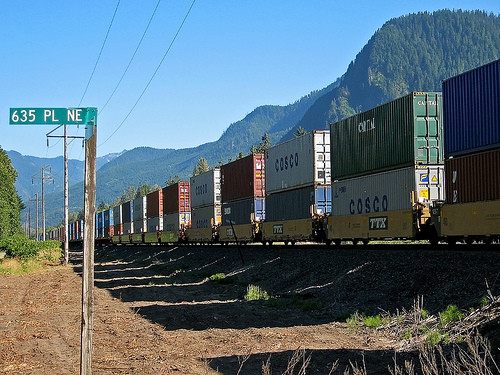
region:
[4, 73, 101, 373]
an address sign with green and white lettering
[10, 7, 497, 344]
a train with double decker cars on it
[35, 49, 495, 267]
a double decker train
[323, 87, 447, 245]
a double decker train with a green top tank and gray lower one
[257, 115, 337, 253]
double decker train cars with a gray one on top and blue on the bottom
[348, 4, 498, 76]
a distant mountain of pine trees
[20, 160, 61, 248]
utility poles in the distance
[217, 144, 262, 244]
a red train car on top and a blue one below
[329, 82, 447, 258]
a green rail car on top and grey one below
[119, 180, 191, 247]
four train cars holding double units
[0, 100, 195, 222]
the sign is green and white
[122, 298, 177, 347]
dirt is on the ground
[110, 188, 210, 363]
train cars cast shadows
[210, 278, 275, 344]
grass is in the dirt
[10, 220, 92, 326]
grass is by the dirt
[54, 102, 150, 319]
the pole is by the street sign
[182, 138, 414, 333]
the train cars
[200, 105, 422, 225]
hills are behind the train cars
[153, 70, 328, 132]
the sky is clear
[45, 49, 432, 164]
power lines are above the train cars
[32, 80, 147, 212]
a sign on a pole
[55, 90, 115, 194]
a signon a metal pole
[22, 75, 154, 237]
a pole with a sign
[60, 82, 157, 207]
a metal pole with sign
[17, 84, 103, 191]
a street gin on a pole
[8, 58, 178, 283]
a street sign on a metal pole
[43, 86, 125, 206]
a pole with a street sgin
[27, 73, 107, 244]
a metal pole with street sign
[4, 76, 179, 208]
a green street sign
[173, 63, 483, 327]
a train on tracks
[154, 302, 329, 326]
THAT IS A SHADOW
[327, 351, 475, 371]
THAT IS A SHADOW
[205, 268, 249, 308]
THAT IS A SHADOW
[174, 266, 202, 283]
THAT IS A SHADOW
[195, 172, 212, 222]
THIS IS A CONTAINER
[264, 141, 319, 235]
THIS IS A CONTAINER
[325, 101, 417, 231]
THIS IS A CONTAINER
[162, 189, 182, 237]
THIS IS A CONTAINER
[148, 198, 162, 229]
THIS IS A CONTAINER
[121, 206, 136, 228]
THIS IS A CONTAINER